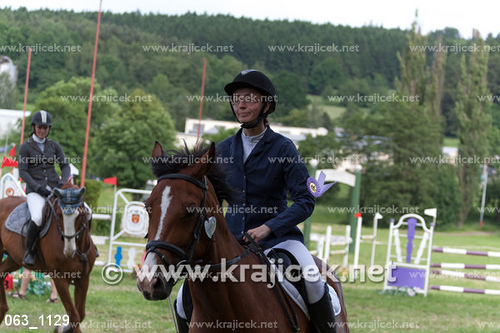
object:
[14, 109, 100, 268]
woman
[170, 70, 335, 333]
rider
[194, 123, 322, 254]
jacket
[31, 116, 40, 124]
black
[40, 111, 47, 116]
white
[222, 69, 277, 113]
helmet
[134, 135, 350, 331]
horse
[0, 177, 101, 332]
horse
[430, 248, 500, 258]
pole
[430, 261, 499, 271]
pole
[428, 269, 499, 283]
pole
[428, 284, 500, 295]
pole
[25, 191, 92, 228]
pants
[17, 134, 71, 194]
jacket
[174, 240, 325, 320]
pants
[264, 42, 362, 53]
watermark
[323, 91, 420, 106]
watermark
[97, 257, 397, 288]
watermark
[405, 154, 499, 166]
watermark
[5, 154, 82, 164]
watermark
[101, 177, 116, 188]
flag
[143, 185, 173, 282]
markings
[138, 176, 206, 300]
face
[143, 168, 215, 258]
something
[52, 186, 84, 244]
something